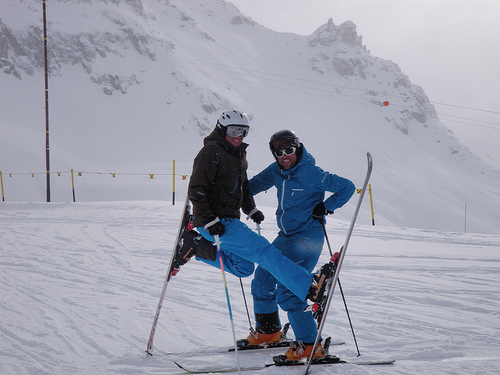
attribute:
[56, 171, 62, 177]
flag — yellow , small  